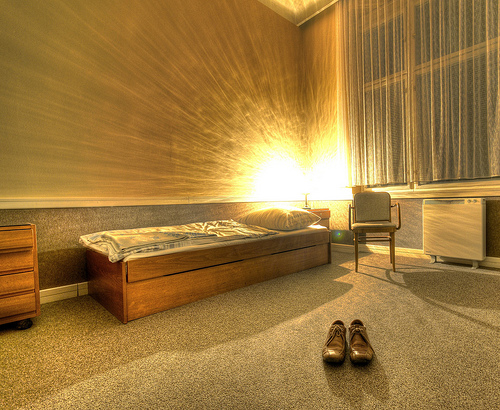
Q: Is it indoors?
A: Yes, it is indoors.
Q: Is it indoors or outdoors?
A: It is indoors.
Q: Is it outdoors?
A: No, it is indoors.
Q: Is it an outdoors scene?
A: No, it is indoors.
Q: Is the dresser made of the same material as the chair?
A: Yes, both the dresser and the chair are made of wood.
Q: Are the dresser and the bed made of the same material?
A: Yes, both the dresser and the bed are made of wood.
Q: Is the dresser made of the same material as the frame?
A: Yes, both the dresser and the frame are made of wood.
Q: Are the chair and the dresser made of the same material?
A: Yes, both the chair and the dresser are made of wood.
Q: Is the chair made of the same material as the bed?
A: Yes, both the chair and the bed are made of wood.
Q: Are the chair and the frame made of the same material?
A: Yes, both the chair and the frame are made of wood.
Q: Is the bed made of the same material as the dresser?
A: Yes, both the bed and the dresser are made of wood.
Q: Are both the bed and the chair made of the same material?
A: Yes, both the bed and the chair are made of wood.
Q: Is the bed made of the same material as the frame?
A: Yes, both the bed and the frame are made of wood.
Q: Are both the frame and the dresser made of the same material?
A: Yes, both the frame and the dresser are made of wood.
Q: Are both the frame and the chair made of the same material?
A: Yes, both the frame and the chair are made of wood.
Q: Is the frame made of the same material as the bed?
A: Yes, both the frame and the bed are made of wood.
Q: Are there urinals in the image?
A: No, there are no urinals.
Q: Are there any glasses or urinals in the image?
A: No, there are no urinals or glasses.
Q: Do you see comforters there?
A: No, there are no comforters.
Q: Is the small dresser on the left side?
A: Yes, the dresser is on the left of the image.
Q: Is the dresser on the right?
A: No, the dresser is on the left of the image.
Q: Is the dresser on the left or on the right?
A: The dresser is on the left of the image.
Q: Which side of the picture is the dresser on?
A: The dresser is on the left of the image.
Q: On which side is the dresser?
A: The dresser is on the left of the image.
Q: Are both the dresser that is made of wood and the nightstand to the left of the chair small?
A: Yes, both the dresser and the nightstand are small.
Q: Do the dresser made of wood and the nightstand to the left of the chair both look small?
A: Yes, both the dresser and the nightstand are small.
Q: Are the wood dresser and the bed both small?
A: Yes, both the dresser and the bed are small.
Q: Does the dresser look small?
A: Yes, the dresser is small.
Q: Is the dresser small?
A: Yes, the dresser is small.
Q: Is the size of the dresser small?
A: Yes, the dresser is small.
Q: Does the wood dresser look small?
A: Yes, the dresser is small.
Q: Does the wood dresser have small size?
A: Yes, the dresser is small.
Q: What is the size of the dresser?
A: The dresser is small.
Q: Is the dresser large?
A: No, the dresser is small.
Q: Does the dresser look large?
A: No, the dresser is small.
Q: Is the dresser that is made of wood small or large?
A: The dresser is small.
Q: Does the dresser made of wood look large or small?
A: The dresser is small.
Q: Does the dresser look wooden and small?
A: Yes, the dresser is wooden and small.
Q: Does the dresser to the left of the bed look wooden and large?
A: No, the dresser is wooden but small.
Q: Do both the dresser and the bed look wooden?
A: Yes, both the dresser and the bed are wooden.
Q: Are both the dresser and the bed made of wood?
A: Yes, both the dresser and the bed are made of wood.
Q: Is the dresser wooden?
A: Yes, the dresser is wooden.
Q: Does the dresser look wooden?
A: Yes, the dresser is wooden.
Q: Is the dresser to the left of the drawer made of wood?
A: Yes, the dresser is made of wood.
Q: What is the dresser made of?
A: The dresser is made of wood.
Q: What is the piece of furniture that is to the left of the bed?
A: The piece of furniture is a dresser.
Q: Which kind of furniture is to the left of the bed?
A: The piece of furniture is a dresser.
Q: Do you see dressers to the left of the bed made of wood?
A: Yes, there is a dresser to the left of the bed.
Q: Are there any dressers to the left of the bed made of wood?
A: Yes, there is a dresser to the left of the bed.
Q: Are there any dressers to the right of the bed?
A: No, the dresser is to the left of the bed.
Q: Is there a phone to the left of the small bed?
A: No, there is a dresser to the left of the bed.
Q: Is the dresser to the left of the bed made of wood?
A: Yes, the dresser is to the left of the bed.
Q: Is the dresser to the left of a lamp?
A: No, the dresser is to the left of the bed.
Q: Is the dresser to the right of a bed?
A: No, the dresser is to the left of a bed.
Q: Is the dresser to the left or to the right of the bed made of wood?
A: The dresser is to the left of the bed.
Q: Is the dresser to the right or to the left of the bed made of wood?
A: The dresser is to the left of the bed.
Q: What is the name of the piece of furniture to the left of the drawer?
A: The piece of furniture is a dresser.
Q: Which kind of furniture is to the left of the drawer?
A: The piece of furniture is a dresser.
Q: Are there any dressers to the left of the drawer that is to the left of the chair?
A: Yes, there is a dresser to the left of the drawer.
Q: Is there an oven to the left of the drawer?
A: No, there is a dresser to the left of the drawer.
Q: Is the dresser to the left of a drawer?
A: Yes, the dresser is to the left of a drawer.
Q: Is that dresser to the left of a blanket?
A: No, the dresser is to the left of a drawer.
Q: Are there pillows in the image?
A: Yes, there is a pillow.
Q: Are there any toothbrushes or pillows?
A: Yes, there is a pillow.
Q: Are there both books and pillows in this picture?
A: No, there is a pillow but no books.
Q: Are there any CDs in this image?
A: No, there are no cds.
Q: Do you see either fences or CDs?
A: No, there are no CDs or fences.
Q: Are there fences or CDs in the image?
A: No, there are no CDs or fences.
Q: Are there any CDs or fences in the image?
A: No, there are no CDs or fences.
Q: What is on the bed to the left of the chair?
A: The pillow is on the bed.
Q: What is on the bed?
A: The pillow is on the bed.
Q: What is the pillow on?
A: The pillow is on the bed.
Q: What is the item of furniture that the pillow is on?
A: The piece of furniture is a bed.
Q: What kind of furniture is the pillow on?
A: The pillow is on the bed.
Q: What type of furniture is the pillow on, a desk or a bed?
A: The pillow is on a bed.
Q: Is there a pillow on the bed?
A: Yes, there is a pillow on the bed.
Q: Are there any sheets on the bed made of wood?
A: No, there is a pillow on the bed.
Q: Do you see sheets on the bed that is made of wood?
A: No, there is a pillow on the bed.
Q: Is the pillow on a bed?
A: Yes, the pillow is on a bed.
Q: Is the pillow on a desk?
A: No, the pillow is on a bed.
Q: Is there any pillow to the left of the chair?
A: Yes, there is a pillow to the left of the chair.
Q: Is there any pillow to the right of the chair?
A: No, the pillow is to the left of the chair.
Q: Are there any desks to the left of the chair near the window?
A: No, there is a pillow to the left of the chair.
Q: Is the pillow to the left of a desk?
A: No, the pillow is to the left of a chair.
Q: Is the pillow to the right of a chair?
A: No, the pillow is to the left of a chair.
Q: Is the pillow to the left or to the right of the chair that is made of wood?
A: The pillow is to the left of the chair.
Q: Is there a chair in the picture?
A: Yes, there is a chair.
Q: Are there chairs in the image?
A: Yes, there is a chair.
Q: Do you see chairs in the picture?
A: Yes, there is a chair.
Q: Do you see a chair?
A: Yes, there is a chair.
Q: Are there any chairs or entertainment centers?
A: Yes, there is a chair.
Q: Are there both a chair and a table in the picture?
A: No, there is a chair but no tables.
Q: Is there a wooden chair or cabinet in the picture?
A: Yes, there is a wood chair.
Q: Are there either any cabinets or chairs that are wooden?
A: Yes, the chair is wooden.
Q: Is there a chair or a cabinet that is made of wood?
A: Yes, the chair is made of wood.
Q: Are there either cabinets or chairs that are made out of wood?
A: Yes, the chair is made of wood.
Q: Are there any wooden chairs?
A: Yes, there is a wood chair.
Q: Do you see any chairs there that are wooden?
A: Yes, there is a chair that is wooden.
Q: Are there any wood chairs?
A: Yes, there is a chair that is made of wood.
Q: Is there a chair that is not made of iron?
A: Yes, there is a chair that is made of wood.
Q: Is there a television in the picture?
A: No, there are no televisions.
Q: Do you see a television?
A: No, there are no televisions.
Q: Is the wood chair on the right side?
A: Yes, the chair is on the right of the image.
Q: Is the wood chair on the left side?
A: No, the chair is on the right of the image.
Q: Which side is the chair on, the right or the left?
A: The chair is on the right of the image.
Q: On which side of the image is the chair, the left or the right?
A: The chair is on the right of the image.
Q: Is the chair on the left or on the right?
A: The chair is on the right of the image.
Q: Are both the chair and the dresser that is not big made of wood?
A: Yes, both the chair and the dresser are made of wood.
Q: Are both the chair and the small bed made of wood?
A: Yes, both the chair and the bed are made of wood.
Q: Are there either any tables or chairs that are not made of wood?
A: No, there is a chair but it is made of wood.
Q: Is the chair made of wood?
A: Yes, the chair is made of wood.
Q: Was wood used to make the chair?
A: Yes, the chair is made of wood.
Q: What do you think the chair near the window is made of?
A: The chair is made of wood.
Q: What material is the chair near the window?
A: The chair is made of wood.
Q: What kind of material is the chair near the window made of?
A: The chair is made of wood.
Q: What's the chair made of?
A: The chair is made of wood.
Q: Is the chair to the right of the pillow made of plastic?
A: No, the chair is made of wood.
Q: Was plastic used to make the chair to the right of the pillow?
A: No, the chair is made of wood.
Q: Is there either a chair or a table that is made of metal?
A: No, there is a chair but it is made of wood.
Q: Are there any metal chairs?
A: No, there is a chair but it is made of wood.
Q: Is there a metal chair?
A: No, there is a chair but it is made of wood.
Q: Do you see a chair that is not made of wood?
A: No, there is a chair but it is made of wood.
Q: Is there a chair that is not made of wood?
A: No, there is a chair but it is made of wood.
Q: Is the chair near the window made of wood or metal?
A: The chair is made of wood.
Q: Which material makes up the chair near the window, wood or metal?
A: The chair is made of wood.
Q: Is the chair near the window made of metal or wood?
A: The chair is made of wood.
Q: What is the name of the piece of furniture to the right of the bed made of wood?
A: The piece of furniture is a chair.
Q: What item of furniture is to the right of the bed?
A: The piece of furniture is a chair.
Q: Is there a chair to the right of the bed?
A: Yes, there is a chair to the right of the bed.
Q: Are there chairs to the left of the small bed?
A: No, the chair is to the right of the bed.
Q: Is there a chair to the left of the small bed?
A: No, the chair is to the right of the bed.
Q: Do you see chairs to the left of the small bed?
A: No, the chair is to the right of the bed.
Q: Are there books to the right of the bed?
A: No, there is a chair to the right of the bed.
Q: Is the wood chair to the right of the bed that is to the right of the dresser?
A: Yes, the chair is to the right of the bed.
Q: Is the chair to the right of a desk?
A: No, the chair is to the right of the bed.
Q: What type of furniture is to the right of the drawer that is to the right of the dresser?
A: The piece of furniture is a chair.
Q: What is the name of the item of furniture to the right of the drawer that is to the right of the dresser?
A: The piece of furniture is a chair.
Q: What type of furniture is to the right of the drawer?
A: The piece of furniture is a chair.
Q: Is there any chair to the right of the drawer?
A: Yes, there is a chair to the right of the drawer.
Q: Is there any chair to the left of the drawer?
A: No, the chair is to the right of the drawer.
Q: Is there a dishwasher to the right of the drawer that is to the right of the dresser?
A: No, there is a chair to the right of the drawer.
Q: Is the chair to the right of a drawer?
A: Yes, the chair is to the right of a drawer.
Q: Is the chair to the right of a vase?
A: No, the chair is to the right of a drawer.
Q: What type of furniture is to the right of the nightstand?
A: The piece of furniture is a chair.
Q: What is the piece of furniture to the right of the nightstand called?
A: The piece of furniture is a chair.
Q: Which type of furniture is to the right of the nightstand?
A: The piece of furniture is a chair.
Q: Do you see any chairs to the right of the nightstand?
A: Yes, there is a chair to the right of the nightstand.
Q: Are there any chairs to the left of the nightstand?
A: No, the chair is to the right of the nightstand.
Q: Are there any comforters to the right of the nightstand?
A: No, there is a chair to the right of the nightstand.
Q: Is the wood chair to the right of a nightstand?
A: Yes, the chair is to the right of a nightstand.